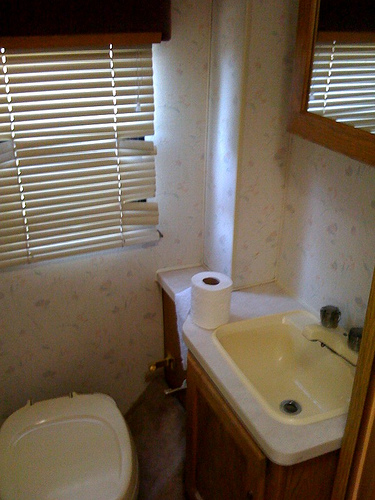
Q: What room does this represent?
A: It represents the bathroom.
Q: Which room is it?
A: It is a bathroom.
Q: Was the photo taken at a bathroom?
A: Yes, it was taken in a bathroom.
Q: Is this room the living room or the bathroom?
A: It is the bathroom.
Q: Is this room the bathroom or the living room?
A: It is the bathroom.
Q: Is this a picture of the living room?
A: No, the picture is showing the bathroom.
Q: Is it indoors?
A: Yes, it is indoors.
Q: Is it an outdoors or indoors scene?
A: It is indoors.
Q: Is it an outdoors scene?
A: No, it is indoors.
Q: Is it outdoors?
A: No, it is indoors.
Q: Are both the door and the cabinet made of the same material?
A: Yes, both the door and the cabinet are made of wood.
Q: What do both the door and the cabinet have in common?
A: The material, both the door and the cabinet are wooden.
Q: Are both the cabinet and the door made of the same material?
A: Yes, both the cabinet and the door are made of wood.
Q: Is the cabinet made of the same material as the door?
A: Yes, both the cabinet and the door are made of wood.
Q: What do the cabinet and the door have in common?
A: The material, both the cabinet and the door are wooden.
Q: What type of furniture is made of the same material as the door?
A: The cabinet is made of the same material as the door.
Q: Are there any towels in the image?
A: No, there are no towels.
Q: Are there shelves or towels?
A: No, there are no towels or shelves.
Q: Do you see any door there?
A: Yes, there is a door.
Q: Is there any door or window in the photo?
A: Yes, there is a door.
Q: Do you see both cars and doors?
A: No, there is a door but no cars.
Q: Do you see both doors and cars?
A: No, there is a door but no cars.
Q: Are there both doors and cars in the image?
A: No, there is a door but no cars.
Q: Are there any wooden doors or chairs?
A: Yes, there is a wood door.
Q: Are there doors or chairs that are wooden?
A: Yes, the door is wooden.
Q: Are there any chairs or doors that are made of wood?
A: Yes, the door is made of wood.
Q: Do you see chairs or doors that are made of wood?
A: Yes, the door is made of wood.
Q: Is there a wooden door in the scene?
A: Yes, there is a wood door.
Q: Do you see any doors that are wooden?
A: Yes, there is a door that is wooden.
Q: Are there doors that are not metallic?
A: Yes, there is a wooden door.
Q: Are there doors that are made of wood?
A: Yes, there is a door that is made of wood.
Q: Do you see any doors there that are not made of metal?
A: Yes, there is a door that is made of wood.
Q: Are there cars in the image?
A: No, there are no cars.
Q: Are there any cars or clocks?
A: No, there are no cars or clocks.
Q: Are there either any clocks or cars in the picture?
A: No, there are no cars or clocks.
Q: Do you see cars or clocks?
A: No, there are no cars or clocks.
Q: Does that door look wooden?
A: Yes, the door is wooden.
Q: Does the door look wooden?
A: Yes, the door is wooden.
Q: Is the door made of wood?
A: Yes, the door is made of wood.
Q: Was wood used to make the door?
A: Yes, the door is made of wood.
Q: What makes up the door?
A: The door is made of wood.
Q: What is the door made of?
A: The door is made of wood.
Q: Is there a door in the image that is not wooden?
A: No, there is a door but it is wooden.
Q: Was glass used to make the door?
A: No, the door is made of wood.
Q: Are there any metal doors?
A: No, there is a door but it is made of wood.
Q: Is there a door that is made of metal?
A: No, there is a door but it is made of wood.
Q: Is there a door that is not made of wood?
A: No, there is a door but it is made of wood.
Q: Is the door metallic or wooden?
A: The door is wooden.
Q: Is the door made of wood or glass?
A: The door is made of wood.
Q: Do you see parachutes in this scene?
A: No, there are no parachutes.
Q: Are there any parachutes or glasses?
A: No, there are no parachutes or glasses.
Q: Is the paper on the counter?
A: Yes, the paper is on the counter.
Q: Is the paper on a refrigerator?
A: No, the paper is on the counter.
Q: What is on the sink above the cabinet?
A: The paper is on the sink.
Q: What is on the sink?
A: The paper is on the sink.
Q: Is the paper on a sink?
A: Yes, the paper is on a sink.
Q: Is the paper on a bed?
A: No, the paper is on a sink.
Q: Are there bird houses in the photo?
A: No, there are no bird houses.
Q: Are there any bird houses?
A: No, there are no bird houses.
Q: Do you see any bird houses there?
A: No, there are no bird houses.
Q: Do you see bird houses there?
A: No, there are no bird houses.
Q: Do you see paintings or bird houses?
A: No, there are no bird houses or paintings.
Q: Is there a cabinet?
A: Yes, there is a cabinet.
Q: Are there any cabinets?
A: Yes, there is a cabinet.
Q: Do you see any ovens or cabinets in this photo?
A: Yes, there is a cabinet.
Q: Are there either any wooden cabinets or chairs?
A: Yes, there is a wood cabinet.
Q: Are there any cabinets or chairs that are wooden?
A: Yes, the cabinet is wooden.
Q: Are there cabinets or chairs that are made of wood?
A: Yes, the cabinet is made of wood.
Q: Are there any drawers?
A: No, there are no drawers.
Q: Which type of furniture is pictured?
A: The furniture is a cabinet.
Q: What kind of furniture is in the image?
A: The furniture is a cabinet.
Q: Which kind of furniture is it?
A: The piece of furniture is a cabinet.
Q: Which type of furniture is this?
A: That is a cabinet.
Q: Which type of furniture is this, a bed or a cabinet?
A: That is a cabinet.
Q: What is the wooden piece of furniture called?
A: The piece of furniture is a cabinet.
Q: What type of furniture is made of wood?
A: The furniture is a cabinet.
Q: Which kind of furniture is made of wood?
A: The furniture is a cabinet.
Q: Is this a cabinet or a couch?
A: This is a cabinet.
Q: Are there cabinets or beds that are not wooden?
A: No, there is a cabinet but it is wooden.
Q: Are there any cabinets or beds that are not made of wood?
A: No, there is a cabinet but it is made of wood.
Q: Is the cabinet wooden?
A: Yes, the cabinet is wooden.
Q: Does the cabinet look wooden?
A: Yes, the cabinet is wooden.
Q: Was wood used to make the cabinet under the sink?
A: Yes, the cabinet is made of wood.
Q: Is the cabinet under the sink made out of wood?
A: Yes, the cabinet is made of wood.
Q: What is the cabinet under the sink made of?
A: The cabinet is made of wood.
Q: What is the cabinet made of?
A: The cabinet is made of wood.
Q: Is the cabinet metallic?
A: No, the cabinet is wooden.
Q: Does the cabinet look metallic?
A: No, the cabinet is wooden.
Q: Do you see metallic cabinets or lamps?
A: No, there is a cabinet but it is wooden.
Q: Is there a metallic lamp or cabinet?
A: No, there is a cabinet but it is wooden.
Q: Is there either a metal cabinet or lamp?
A: No, there is a cabinet but it is wooden.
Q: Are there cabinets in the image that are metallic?
A: No, there is a cabinet but it is wooden.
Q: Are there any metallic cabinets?
A: No, there is a cabinet but it is wooden.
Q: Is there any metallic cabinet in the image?
A: No, there is a cabinet but it is wooden.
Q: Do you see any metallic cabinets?
A: No, there is a cabinet but it is wooden.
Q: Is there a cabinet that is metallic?
A: No, there is a cabinet but it is wooden.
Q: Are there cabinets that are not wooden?
A: No, there is a cabinet but it is wooden.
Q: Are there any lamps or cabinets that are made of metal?
A: No, there is a cabinet but it is made of wood.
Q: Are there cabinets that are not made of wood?
A: No, there is a cabinet but it is made of wood.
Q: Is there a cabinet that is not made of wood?
A: No, there is a cabinet but it is made of wood.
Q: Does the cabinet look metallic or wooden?
A: The cabinet is wooden.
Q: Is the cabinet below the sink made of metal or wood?
A: The cabinet is made of wood.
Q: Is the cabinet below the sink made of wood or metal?
A: The cabinet is made of wood.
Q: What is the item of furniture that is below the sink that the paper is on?
A: The piece of furniture is a cabinet.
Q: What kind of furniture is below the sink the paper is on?
A: The piece of furniture is a cabinet.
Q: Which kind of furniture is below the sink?
A: The piece of furniture is a cabinet.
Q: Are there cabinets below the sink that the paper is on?
A: Yes, there is a cabinet below the sink.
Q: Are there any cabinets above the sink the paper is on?
A: No, the cabinet is below the sink.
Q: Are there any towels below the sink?
A: No, there is a cabinet below the sink.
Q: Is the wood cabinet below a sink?
A: Yes, the cabinet is below a sink.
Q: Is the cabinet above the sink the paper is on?
A: No, the cabinet is below the sink.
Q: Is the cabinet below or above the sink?
A: The cabinet is below the sink.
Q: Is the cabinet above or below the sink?
A: The cabinet is below the sink.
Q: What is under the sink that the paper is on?
A: The cabinet is under the sink.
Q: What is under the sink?
A: The cabinet is under the sink.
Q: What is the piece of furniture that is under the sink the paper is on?
A: The piece of furniture is a cabinet.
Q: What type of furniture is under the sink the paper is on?
A: The piece of furniture is a cabinet.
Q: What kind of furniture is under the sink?
A: The piece of furniture is a cabinet.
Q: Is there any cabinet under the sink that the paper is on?
A: Yes, there is a cabinet under the sink.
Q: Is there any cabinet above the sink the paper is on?
A: No, the cabinet is under the sink.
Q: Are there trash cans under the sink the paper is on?
A: No, there is a cabinet under the sink.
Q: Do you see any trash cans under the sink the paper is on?
A: No, there is a cabinet under the sink.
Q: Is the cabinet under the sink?
A: Yes, the cabinet is under the sink.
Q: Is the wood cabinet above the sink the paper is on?
A: No, the cabinet is under the sink.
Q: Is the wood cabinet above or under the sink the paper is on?
A: The cabinet is under the sink.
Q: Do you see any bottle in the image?
A: No, there are no bottles.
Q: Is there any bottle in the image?
A: No, there are no bottles.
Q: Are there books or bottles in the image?
A: No, there are no bottles or books.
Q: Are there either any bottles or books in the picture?
A: No, there are no bottles or books.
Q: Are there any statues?
A: No, there are no statues.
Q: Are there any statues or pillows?
A: No, there are no statues or pillows.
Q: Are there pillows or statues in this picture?
A: No, there are no statues or pillows.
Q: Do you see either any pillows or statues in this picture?
A: No, there are no statues or pillows.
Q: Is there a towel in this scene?
A: No, there are no towels.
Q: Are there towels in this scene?
A: No, there are no towels.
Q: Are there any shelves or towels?
A: No, there are no towels or shelves.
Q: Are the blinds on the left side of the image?
A: Yes, the blinds are on the left of the image.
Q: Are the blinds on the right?
A: No, the blinds are on the left of the image.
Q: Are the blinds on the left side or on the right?
A: The blinds are on the left of the image.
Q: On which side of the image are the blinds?
A: The blinds are on the left of the image.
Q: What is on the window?
A: The blinds are on the window.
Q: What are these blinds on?
A: The blinds are on the window.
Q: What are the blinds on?
A: The blinds are on the window.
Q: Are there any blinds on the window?
A: Yes, there are blinds on the window.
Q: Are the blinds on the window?
A: Yes, the blinds are on the window.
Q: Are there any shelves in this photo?
A: No, there are no shelves.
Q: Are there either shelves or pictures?
A: No, there are no shelves or pictures.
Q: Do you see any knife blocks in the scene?
A: No, there are no knife blocks.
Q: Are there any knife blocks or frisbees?
A: No, there are no knife blocks or frisbees.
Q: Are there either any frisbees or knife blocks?
A: No, there are no knife blocks or frisbees.